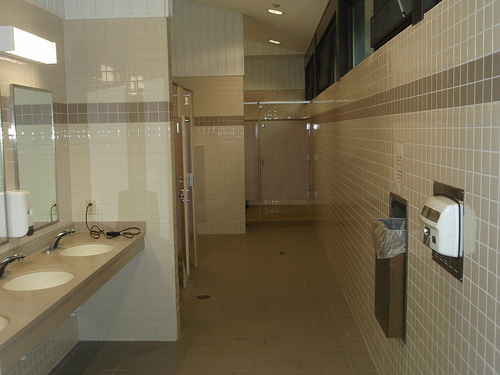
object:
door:
[257, 117, 313, 202]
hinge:
[305, 153, 311, 161]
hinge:
[305, 185, 311, 200]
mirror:
[8, 85, 63, 232]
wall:
[1, 1, 71, 373]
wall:
[304, 2, 498, 373]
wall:
[159, 0, 250, 233]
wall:
[241, 22, 316, 205]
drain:
[193, 293, 211, 300]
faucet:
[40, 227, 76, 255]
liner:
[370, 215, 409, 260]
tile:
[465, 104, 476, 127]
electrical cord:
[84, 203, 141, 240]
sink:
[55, 240, 115, 258]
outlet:
[81, 194, 99, 219]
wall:
[55, 0, 186, 347]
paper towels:
[4, 189, 30, 239]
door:
[175, 113, 198, 287]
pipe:
[243, 99, 311, 105]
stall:
[243, 116, 318, 226]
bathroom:
[0, 0, 499, 375]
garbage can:
[369, 216, 407, 340]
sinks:
[1, 269, 76, 292]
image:
[463, 204, 480, 258]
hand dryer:
[416, 192, 461, 260]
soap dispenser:
[2, 189, 36, 240]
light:
[2, 22, 67, 69]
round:
[188, 233, 298, 375]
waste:
[370, 215, 409, 339]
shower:
[257, 103, 264, 222]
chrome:
[51, 255, 65, 267]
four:
[224, 91, 301, 190]